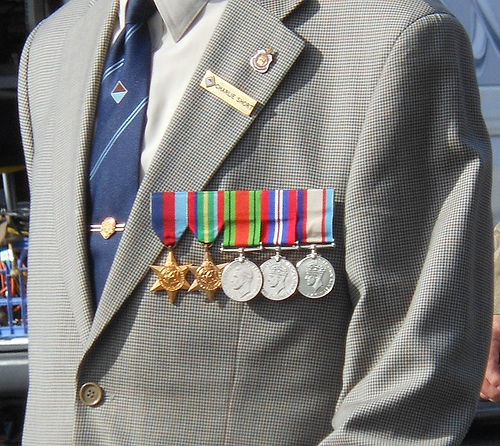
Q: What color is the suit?
A: Plaid.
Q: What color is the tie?
A: Blue.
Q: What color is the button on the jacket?
A: Beige.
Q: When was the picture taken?
A: Daytime.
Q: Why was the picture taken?
A: To celebrate his achievements.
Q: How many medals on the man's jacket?
A: Five.